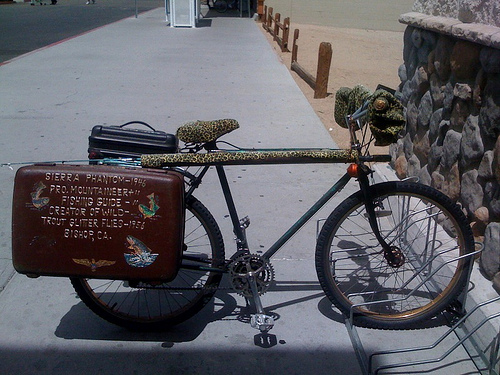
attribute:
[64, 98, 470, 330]
bicycle — parked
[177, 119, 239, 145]
seat — printed, leopard print, cheetah print, patterned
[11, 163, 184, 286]
suitcase — brown, maroon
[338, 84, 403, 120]
handlebars — cheetah print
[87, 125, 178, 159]
case — black, small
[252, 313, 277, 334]
pedal — metal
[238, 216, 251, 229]
pedal — metal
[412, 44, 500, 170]
rock wall — gray, brown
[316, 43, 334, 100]
pole — wooden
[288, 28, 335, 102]
fence — broken, wooden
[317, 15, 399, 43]
sand — golden brown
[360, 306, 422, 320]
rim — gold